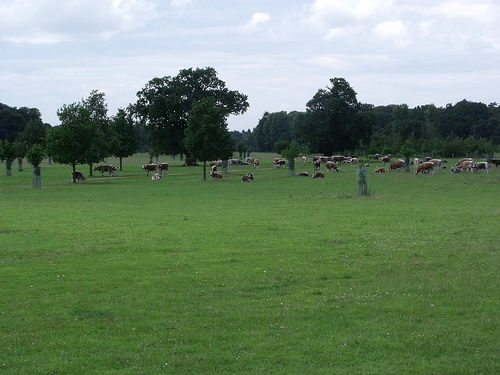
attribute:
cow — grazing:
[140, 162, 158, 178]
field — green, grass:
[2, 151, 500, 373]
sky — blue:
[1, 0, 499, 135]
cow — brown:
[93, 164, 119, 177]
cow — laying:
[207, 169, 227, 179]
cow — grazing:
[70, 170, 90, 183]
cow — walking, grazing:
[389, 159, 406, 172]